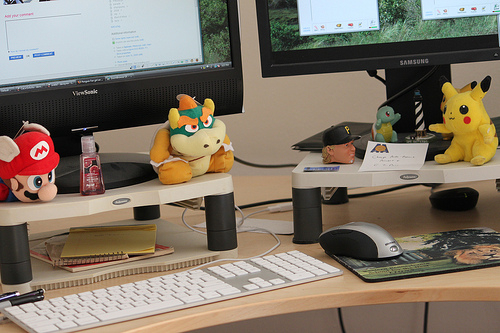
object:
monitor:
[252, 0, 500, 76]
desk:
[1, 143, 500, 332]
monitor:
[2, 1, 244, 139]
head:
[323, 124, 360, 165]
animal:
[425, 75, 500, 167]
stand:
[289, 123, 499, 245]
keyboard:
[2, 247, 347, 332]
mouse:
[317, 221, 404, 260]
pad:
[329, 227, 497, 284]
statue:
[405, 88, 434, 140]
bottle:
[75, 136, 107, 197]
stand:
[1, 153, 241, 295]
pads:
[43, 238, 129, 266]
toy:
[0, 122, 63, 205]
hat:
[0, 124, 59, 178]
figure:
[149, 93, 234, 184]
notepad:
[61, 224, 154, 257]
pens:
[1, 289, 22, 298]